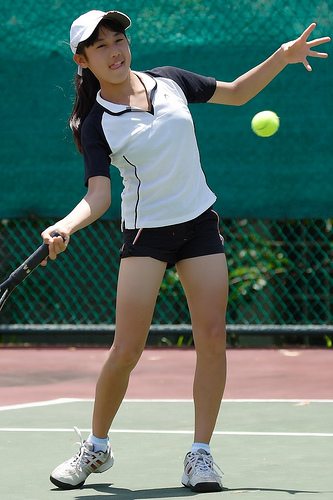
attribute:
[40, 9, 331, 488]
girl — little, playing tennis, caucasian, young, asian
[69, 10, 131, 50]
hat — blocking sun, white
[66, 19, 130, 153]
hair — long, black, in ponytail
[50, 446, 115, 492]
shoe — white, red accented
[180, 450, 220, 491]
shoe — white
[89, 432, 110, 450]
sock — ankle high, white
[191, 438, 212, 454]
sock — white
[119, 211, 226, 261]
shorts — too short, black, short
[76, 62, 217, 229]
shirt — white, black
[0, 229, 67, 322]
racket — black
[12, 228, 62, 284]
grip — black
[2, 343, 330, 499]
tennis court — red sectioned, green, brown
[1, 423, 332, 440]
line — white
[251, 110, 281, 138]
tennis ball — flourescent, in air, flying in air, yellow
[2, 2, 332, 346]
fence — blue, green, chain link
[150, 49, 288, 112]
arm — sunny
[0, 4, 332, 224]
net — green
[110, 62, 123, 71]
tongue — out in concentration